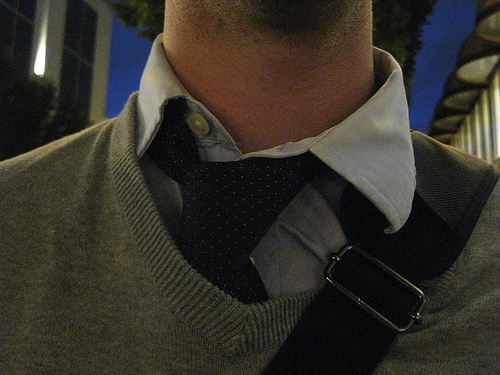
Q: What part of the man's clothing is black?
A: The necktie.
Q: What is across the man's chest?
A: A black strap.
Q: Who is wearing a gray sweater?
A: The man.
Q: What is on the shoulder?
A: Straps.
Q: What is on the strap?
A: Buckle.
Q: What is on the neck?
A: Tie.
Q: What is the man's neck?
A: White collar.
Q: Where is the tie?
A: Neck.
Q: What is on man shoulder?
A: Bag.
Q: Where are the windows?
A: Behind man.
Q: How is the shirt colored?
A: White.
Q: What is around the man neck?
A: A tie.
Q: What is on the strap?
A: Metal clasp.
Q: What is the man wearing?
A: Gray sweater.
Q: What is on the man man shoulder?
A: Black and grey strap.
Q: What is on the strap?
A: Metal attachment.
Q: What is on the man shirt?
A: Tie.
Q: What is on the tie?
A: White dots.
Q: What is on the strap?
A: Shoulder pad.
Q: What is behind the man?
A: A bush.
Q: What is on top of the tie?
A: A knot.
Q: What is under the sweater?
A: Dress shirt.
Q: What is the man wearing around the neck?
A: Tie.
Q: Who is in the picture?
A: A man.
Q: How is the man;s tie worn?
A: Loosely.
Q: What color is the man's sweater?
A: Grey.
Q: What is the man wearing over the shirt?
A: A sweater.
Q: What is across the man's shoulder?
A: A strap.